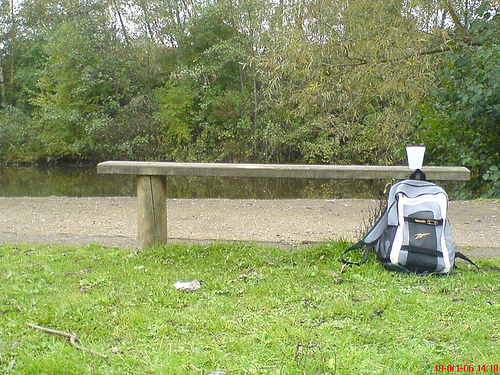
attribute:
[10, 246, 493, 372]
grass — green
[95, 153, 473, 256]
bench — wooden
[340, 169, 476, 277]
backpack — leaning, resting, blue gray, gray, white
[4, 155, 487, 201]
lake — raised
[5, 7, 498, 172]
trees — green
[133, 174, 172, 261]
leg — wooden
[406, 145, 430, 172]
cup — white